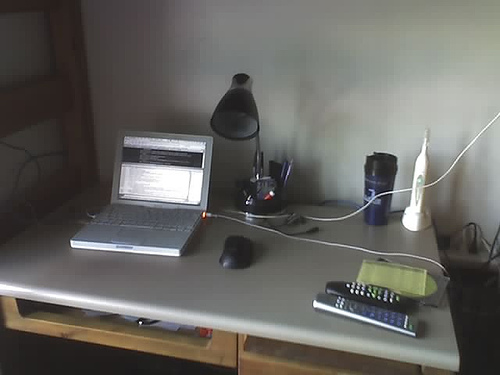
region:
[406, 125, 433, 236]
an electric toothbrush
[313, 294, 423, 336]
a silver remote control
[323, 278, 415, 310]
a black remote control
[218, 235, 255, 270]
a black computer mouse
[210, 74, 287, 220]
a black desk lamp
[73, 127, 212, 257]
a silver laptop computer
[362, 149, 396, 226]
a blue cup with a black lid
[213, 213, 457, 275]
a cord to the laptop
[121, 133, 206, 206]
screen on a laptop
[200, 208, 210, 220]
power indicator light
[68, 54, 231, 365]
Lap top on the table.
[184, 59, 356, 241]
Lamp on the table.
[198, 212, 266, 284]
Mouse on the table.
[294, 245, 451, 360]
Remotes on the table.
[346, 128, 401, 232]
Cup on the table.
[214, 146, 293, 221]
Pencils in the holder.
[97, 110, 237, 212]
Screen on the laptop.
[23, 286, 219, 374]
Drawer under the desk.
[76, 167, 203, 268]
Keyboard on the laptop.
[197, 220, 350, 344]
Black mouse on the table.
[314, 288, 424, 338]
a silver tv remote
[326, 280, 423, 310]
a black tv remote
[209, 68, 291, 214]
a black table top lamp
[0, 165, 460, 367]
a small computer desk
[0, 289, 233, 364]
a cuby under the desk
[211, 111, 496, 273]
white cords attached to the laptop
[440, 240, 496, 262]
a white power strip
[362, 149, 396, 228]
a blue and black thermos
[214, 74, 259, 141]
black shade of lamp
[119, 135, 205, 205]
glowing screen of laptop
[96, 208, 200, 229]
buttons on laptop keyboard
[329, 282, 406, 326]
buttons on two remote controls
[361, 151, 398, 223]
blue and black cup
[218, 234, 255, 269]
top of black computer mouse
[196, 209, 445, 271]
wire plugged in side of computer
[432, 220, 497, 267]
wires plugged into strips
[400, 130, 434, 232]
electric brush in base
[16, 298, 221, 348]
open drawer under table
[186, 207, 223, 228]
edge of white power cord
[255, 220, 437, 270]
long white power cord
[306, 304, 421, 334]
long silver remote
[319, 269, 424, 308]
black remote on table top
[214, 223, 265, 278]
black remote on table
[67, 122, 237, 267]
small silver lap top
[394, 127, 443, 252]
white charger on table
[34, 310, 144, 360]
wood base on silver table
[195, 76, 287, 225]
black lamp with shade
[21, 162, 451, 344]
large silver table top